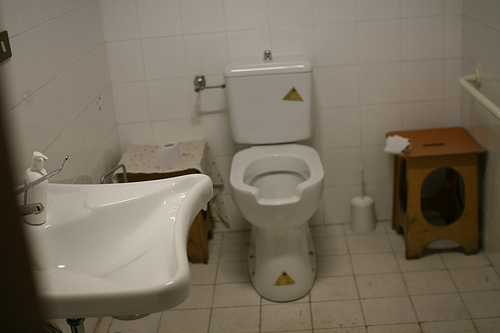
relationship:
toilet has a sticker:
[223, 54, 326, 304] [281, 88, 302, 103]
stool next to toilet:
[385, 127, 489, 261] [223, 54, 326, 304]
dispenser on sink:
[23, 151, 49, 226] [14, 173, 215, 319]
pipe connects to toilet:
[193, 75, 226, 93] [223, 54, 326, 304]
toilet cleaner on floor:
[351, 165, 377, 236] [97, 220, 499, 333]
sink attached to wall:
[14, 173, 215, 319] [0, 0, 121, 332]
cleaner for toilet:
[351, 165, 377, 236] [223, 54, 326, 304]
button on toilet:
[263, 49, 272, 62] [223, 54, 326, 304]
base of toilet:
[229, 144, 324, 303] [223, 54, 326, 304]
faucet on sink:
[13, 156, 68, 218] [14, 173, 215, 319]